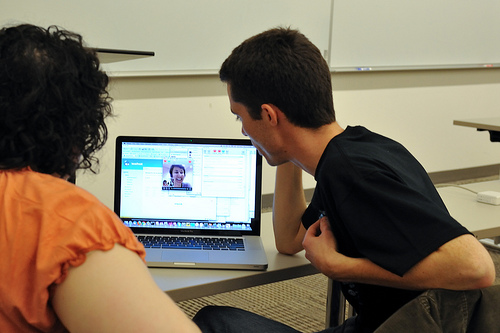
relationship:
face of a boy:
[163, 161, 194, 187] [165, 161, 182, 187]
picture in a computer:
[135, 153, 238, 224] [118, 133, 283, 279]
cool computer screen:
[118, 133, 283, 279] [119, 140, 263, 227]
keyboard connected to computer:
[134, 229, 265, 274] [118, 133, 283, 279]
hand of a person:
[294, 218, 345, 270] [223, 33, 458, 280]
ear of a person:
[254, 97, 281, 137] [223, 33, 458, 280]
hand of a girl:
[294, 218, 345, 270] [7, 15, 179, 314]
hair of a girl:
[13, 23, 83, 155] [7, 15, 179, 314]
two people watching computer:
[1, 12, 406, 315] [118, 133, 283, 279]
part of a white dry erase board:
[132, 9, 221, 52] [108, 7, 212, 39]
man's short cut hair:
[246, 25, 309, 110] [13, 23, 83, 155]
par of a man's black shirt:
[223, 33, 458, 280] [318, 126, 422, 242]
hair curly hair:
[0, 23, 113, 179] [13, 23, 83, 155]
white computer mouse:
[474, 187, 496, 208] [461, 176, 497, 210]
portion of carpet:
[285, 279, 314, 316] [272, 280, 315, 309]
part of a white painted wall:
[132, 9, 221, 52] [383, 85, 435, 142]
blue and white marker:
[109, 47, 195, 92] [103, 43, 255, 141]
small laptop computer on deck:
[118, 133, 283, 279] [118, 139, 328, 330]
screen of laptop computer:
[119, 140, 263, 227] [118, 133, 283, 279]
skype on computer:
[126, 144, 193, 231] [118, 133, 283, 279]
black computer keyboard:
[118, 133, 283, 279] [134, 229, 265, 274]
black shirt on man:
[318, 126, 422, 242] [223, 33, 458, 280]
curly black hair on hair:
[13, 23, 83, 155] [0, 23, 113, 179]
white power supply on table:
[474, 187, 496, 208] [463, 149, 499, 216]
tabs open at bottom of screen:
[130, 209, 281, 239] [119, 140, 263, 227]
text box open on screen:
[198, 148, 257, 209] [119, 140, 263, 227]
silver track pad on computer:
[161, 244, 218, 273] [118, 133, 283, 279]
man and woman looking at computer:
[1, 12, 406, 315] [118, 133, 283, 279]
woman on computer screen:
[7, 15, 179, 314] [119, 140, 263, 227]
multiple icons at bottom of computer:
[128, 217, 257, 235] [118, 133, 283, 279]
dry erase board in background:
[114, 15, 241, 25] [74, 5, 482, 64]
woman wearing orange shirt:
[7, 15, 179, 314] [11, 179, 116, 258]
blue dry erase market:
[348, 65, 371, 73] [354, 64, 374, 77]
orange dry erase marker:
[474, 62, 493, 73] [103, 43, 255, 141]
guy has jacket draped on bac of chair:
[223, 33, 458, 280] [402, 275, 468, 329]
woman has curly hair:
[7, 15, 179, 314] [13, 23, 83, 155]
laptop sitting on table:
[118, 133, 283, 279] [463, 149, 499, 216]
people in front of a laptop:
[1, 12, 406, 315] [118, 133, 283, 279]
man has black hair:
[223, 33, 458, 280] [205, 19, 341, 134]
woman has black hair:
[7, 15, 179, 314] [205, 19, 341, 134]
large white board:
[100, 4, 449, 44] [108, 7, 212, 39]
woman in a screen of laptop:
[163, 161, 194, 187] [118, 133, 283, 279]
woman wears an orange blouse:
[7, 15, 179, 314] [11, 179, 116, 258]